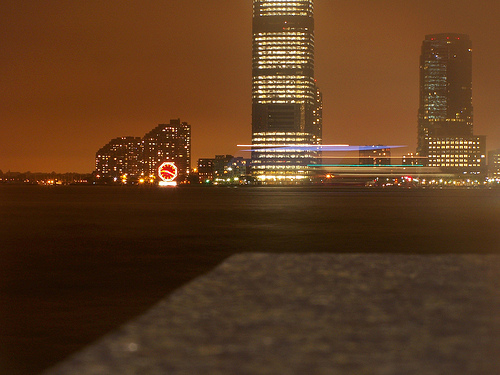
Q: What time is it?
A: Evening.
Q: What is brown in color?
A: Sky.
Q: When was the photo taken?
A: Night.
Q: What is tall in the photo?
A: Building.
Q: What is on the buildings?
A: Windows.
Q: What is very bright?
A: Lights.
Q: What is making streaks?
A: The lights.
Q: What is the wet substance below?
A: Water.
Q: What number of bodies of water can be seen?
A: One.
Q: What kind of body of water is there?
A: An ocean.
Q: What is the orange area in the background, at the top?
A: The sky.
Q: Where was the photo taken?
A: Outside somewhere.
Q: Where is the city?
A: Next to the water.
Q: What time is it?
A: Evening.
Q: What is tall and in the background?
A: A building.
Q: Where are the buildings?
A: Near the water.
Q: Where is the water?
A: In front of the buildings.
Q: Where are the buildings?
A: In the distance.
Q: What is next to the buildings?
A: Water.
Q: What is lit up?
A: The buildings.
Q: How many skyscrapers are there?
A: Two.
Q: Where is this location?
A: In a big city.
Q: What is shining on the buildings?
A: Lights from inside.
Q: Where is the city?
A: Across from a lake.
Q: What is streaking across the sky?
A: Lights.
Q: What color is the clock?
A: Red.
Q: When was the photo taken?
A: At night.